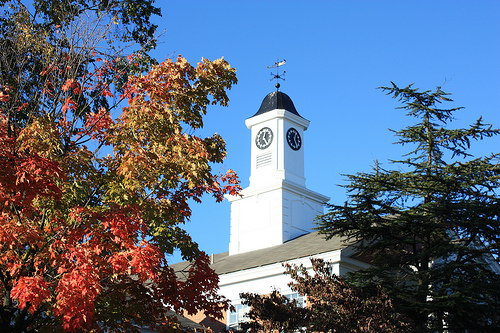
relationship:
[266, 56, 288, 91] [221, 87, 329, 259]
weather vane on top of tower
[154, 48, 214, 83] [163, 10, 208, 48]
cloud in sky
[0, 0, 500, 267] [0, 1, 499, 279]
cloud in sky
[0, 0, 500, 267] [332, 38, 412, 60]
cloud in sky